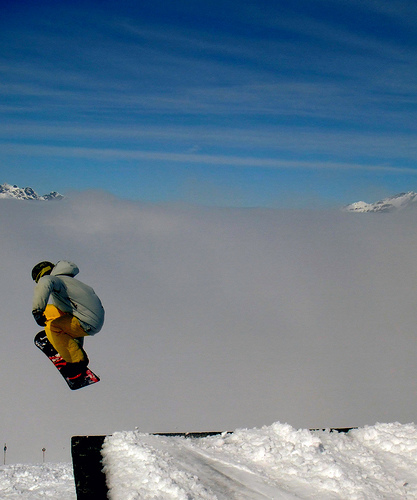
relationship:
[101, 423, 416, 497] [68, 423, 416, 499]
snow on ramp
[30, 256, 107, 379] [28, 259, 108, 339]
guy in jacket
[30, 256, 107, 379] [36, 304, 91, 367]
guy in pants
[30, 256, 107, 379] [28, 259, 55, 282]
guy with safety helmet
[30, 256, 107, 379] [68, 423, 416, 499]
guy jumped off ramp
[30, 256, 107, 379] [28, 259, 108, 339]
guy wearing jacket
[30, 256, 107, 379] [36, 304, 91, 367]
guy wearing pants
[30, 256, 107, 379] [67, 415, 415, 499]
guy jumped off slope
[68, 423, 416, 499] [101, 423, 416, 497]
ramp with snow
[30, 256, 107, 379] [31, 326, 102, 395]
guy jumping on snowboard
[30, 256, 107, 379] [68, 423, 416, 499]
guy launches off ramp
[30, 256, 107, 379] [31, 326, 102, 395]
guy on snowboard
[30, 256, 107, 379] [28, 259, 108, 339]
guy with jacket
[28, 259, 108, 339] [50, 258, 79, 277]
jacket has hood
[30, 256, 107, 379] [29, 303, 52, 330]
guy has gloves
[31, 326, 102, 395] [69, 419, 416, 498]
snowboard going off jump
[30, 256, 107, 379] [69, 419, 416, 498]
guy went off jump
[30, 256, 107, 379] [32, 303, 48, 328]
guy wearing glove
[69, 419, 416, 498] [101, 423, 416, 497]
jump has snow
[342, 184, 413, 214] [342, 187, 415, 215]
mountain has top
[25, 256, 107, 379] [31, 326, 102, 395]
guy on snowboard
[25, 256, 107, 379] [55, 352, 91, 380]
guy has boot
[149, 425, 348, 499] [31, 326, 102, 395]
snowboard tracks left by snowboard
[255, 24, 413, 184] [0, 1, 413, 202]
clouds in sky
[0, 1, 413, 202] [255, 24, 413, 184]
sky has clouds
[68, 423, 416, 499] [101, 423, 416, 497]
ramp covered in snow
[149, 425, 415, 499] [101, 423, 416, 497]
snowboard tracks in snow